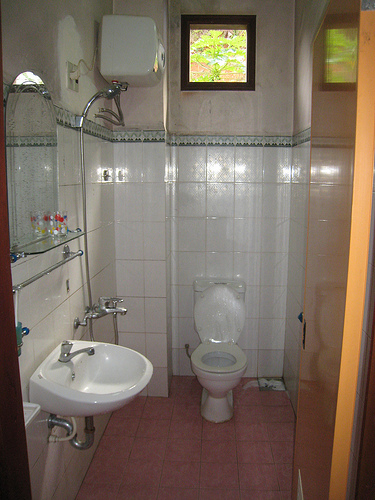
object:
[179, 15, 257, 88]
window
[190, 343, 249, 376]
toilet seat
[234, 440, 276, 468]
tile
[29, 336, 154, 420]
sink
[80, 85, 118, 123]
shower head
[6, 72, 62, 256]
mirror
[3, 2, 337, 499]
wall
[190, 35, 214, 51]
leaves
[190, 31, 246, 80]
tree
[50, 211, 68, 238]
cup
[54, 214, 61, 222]
dots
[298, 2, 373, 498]
door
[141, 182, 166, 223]
tile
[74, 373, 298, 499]
floor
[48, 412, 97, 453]
pipe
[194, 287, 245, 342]
lid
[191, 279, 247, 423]
bathroom toilet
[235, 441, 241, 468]
grout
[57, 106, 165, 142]
wall paper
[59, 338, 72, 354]
knob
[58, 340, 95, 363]
faucet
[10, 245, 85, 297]
towel rack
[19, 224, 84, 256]
shelf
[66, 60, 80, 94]
outlet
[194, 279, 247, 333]
water tank